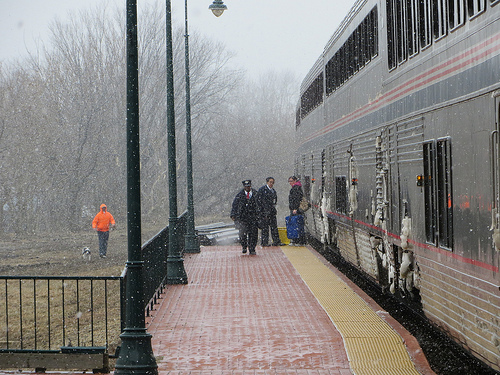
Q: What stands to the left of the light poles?
A: A metal fence.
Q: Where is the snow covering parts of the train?
A: On the side.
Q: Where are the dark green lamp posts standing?
A: On the platform.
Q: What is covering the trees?
A: Snowfall.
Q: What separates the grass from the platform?
A: A dark metal fence.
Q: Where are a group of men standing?
A: Beside train.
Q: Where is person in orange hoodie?
A: In grass on left.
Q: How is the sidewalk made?
A: With red bricks.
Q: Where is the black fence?
A: Bordering the sidewalk.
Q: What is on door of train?
A: Ice and snow.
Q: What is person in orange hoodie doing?
A: Walking a dog.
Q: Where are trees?
A: In the background behind train.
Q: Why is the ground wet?
A: It's snowing.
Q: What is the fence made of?
A: Black metal.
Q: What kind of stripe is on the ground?
A: A long yellow stripe.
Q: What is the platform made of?
A: Red brick.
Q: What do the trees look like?
A: Tall and bare.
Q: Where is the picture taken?
A: At a train stop.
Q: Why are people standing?
A: To board the rain.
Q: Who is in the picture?
A: 4 men.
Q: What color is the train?
A: Gray.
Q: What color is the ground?
A: Red.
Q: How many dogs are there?
A: One.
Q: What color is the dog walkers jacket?
A: Orange.